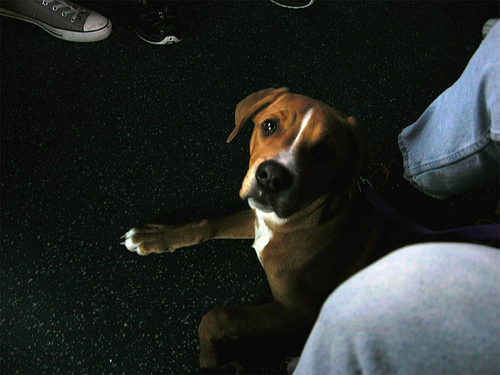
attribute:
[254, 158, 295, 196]
nose — black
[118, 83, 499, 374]
dog — white, looking up, brown, looking at camera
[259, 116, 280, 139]
eye — black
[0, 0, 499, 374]
ground — concrete, speckled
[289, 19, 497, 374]
jeans — blue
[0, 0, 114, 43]
shoe — grey, white, converse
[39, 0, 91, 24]
lace — white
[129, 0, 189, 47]
shoe — black, white, athletic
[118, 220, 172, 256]
paw — brown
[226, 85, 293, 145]
ear — brown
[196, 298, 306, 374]
front leg — bent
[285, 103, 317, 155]
marking — white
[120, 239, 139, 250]
toe — white